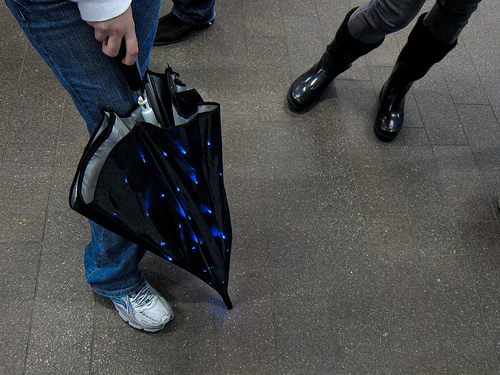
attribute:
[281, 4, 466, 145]
boots — dark, black, large, shiny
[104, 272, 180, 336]
shoe — white, light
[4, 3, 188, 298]
jeans — blue , dark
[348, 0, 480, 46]
pants — dark, grey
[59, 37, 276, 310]
umbrella — dark, blue, black, large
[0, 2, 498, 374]
floor — grey, brown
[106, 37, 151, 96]
handle — dark, black 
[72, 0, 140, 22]
shirt — white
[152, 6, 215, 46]
shoe — dark, black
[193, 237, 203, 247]
light — blue 